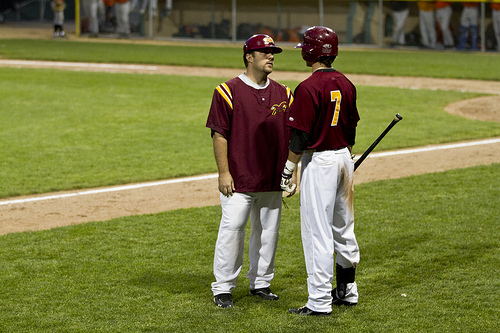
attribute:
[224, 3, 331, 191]
players — standing, talking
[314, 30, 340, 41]
helmet — here, worn, maroon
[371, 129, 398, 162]
bat — here, held, black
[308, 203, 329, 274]
trousers — white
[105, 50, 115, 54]
grass — here, short, green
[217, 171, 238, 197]
hand — here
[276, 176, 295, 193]
glove — white, black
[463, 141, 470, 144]
line — white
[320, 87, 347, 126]
number — 7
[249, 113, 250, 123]
jersey — maroon, white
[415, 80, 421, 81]
dirt — ground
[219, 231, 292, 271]
pants — white, dirty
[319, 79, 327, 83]
shirt — maroon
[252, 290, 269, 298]
shoes — black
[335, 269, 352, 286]
cleats — black